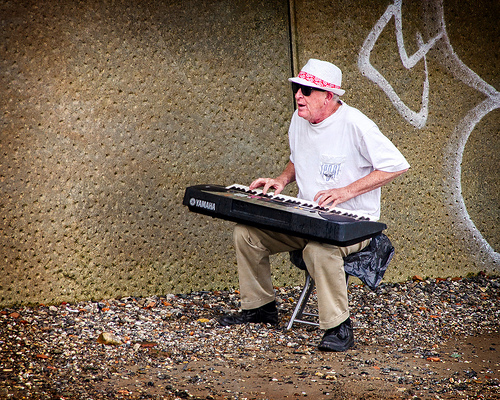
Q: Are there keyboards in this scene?
A: Yes, there is a keyboard.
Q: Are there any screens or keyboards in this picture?
A: Yes, there is a keyboard.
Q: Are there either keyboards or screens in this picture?
A: Yes, there is a keyboard.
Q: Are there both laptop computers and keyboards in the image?
A: No, there is a keyboard but no laptops.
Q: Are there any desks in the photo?
A: No, there are no desks.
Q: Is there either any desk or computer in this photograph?
A: No, there are no desks or computers.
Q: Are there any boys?
A: No, there are no boys.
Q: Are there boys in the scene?
A: No, there are no boys.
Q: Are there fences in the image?
A: No, there are no fences.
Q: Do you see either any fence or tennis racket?
A: No, there are no fences or rackets.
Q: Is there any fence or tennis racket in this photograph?
A: No, there are no fences or rackets.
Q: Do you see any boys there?
A: No, there are no boys.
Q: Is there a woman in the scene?
A: No, there are no women.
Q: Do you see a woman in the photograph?
A: No, there are no women.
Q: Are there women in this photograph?
A: No, there are no women.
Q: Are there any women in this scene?
A: No, there are no women.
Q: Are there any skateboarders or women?
A: No, there are no women or skateboarders.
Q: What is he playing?
A: The man is playing the keyboard.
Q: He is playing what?
A: The man is playing the keyboard.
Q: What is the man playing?
A: The man is playing the keyboard.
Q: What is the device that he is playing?
A: The device is a keyboard.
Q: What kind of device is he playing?
A: The man is playing the keyboard.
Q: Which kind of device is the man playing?
A: The man is playing the keyboard.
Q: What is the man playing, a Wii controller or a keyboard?
A: The man is playing a keyboard.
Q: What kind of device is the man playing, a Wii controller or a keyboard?
A: The man is playing a keyboard.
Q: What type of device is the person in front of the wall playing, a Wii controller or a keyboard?
A: The man is playing a keyboard.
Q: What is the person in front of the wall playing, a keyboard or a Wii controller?
A: The man is playing a keyboard.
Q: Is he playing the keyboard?
A: Yes, the man is playing the keyboard.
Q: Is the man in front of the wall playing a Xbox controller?
A: No, the man is playing the keyboard.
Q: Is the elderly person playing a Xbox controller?
A: No, the man is playing the keyboard.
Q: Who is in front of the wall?
A: The man is in front of the wall.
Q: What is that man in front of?
A: The man is in front of the wall.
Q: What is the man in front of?
A: The man is in front of the wall.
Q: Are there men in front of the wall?
A: Yes, there is a man in front of the wall.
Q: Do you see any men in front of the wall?
A: Yes, there is a man in front of the wall.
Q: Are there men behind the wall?
A: No, the man is in front of the wall.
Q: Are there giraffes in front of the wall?
A: No, there is a man in front of the wall.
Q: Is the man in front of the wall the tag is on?
A: Yes, the man is in front of the wall.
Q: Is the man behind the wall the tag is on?
A: No, the man is in front of the wall.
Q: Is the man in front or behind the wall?
A: The man is in front of the wall.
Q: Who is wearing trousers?
A: The man is wearing trousers.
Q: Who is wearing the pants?
A: The man is wearing trousers.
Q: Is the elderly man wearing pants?
A: Yes, the man is wearing pants.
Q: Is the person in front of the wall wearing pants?
A: Yes, the man is wearing pants.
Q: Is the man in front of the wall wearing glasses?
A: No, the man is wearing pants.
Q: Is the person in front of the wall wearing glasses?
A: No, the man is wearing pants.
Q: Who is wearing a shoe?
A: The man is wearing a shoe.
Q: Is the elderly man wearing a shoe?
A: Yes, the man is wearing a shoe.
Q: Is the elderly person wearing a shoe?
A: Yes, the man is wearing a shoe.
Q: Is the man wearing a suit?
A: No, the man is wearing a shoe.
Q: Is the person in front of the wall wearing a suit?
A: No, the man is wearing a shoe.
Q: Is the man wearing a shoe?
A: Yes, the man is wearing a shoe.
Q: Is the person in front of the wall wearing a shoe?
A: Yes, the man is wearing a shoe.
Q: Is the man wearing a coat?
A: No, the man is wearing a shoe.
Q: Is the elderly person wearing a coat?
A: No, the man is wearing a shoe.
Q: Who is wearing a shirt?
A: The man is wearing a shirt.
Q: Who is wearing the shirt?
A: The man is wearing a shirt.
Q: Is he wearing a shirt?
A: Yes, the man is wearing a shirt.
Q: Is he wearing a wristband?
A: No, the man is wearing a shirt.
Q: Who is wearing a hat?
A: The man is wearing a hat.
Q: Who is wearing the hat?
A: The man is wearing a hat.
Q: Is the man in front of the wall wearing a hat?
A: Yes, the man is wearing a hat.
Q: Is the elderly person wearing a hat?
A: Yes, the man is wearing a hat.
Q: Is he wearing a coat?
A: No, the man is wearing a hat.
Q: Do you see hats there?
A: Yes, there is a hat.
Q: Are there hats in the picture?
A: Yes, there is a hat.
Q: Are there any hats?
A: Yes, there is a hat.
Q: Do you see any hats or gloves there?
A: Yes, there is a hat.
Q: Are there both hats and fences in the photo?
A: No, there is a hat but no fences.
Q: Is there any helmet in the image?
A: No, there are no helmets.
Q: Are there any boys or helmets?
A: No, there are no helmets or boys.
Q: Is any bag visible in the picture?
A: Yes, there is a bag.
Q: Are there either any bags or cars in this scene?
A: Yes, there is a bag.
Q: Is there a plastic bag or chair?
A: Yes, there is a plastic bag.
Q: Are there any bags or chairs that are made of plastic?
A: Yes, the bag is made of plastic.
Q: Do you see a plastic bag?
A: Yes, there is a bag that is made of plastic.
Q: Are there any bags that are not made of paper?
A: Yes, there is a bag that is made of plastic.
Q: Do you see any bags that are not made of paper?
A: Yes, there is a bag that is made of plastic.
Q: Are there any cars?
A: No, there are no cars.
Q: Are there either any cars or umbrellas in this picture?
A: No, there are no cars or umbrellas.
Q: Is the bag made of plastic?
A: Yes, the bag is made of plastic.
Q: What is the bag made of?
A: The bag is made of plastic.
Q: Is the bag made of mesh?
A: No, the bag is made of plastic.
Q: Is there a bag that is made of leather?
A: No, there is a bag but it is made of plastic.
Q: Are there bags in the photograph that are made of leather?
A: No, there is a bag but it is made of plastic.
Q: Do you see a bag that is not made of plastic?
A: No, there is a bag but it is made of plastic.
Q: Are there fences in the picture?
A: No, there are no fences.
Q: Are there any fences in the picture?
A: No, there are no fences.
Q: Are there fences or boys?
A: No, there are no fences or boys.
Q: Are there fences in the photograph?
A: No, there are no fences.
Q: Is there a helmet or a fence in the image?
A: No, there are no fences or helmets.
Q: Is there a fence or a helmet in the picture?
A: No, there are no fences or helmets.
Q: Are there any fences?
A: No, there are no fences.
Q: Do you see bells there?
A: No, there are no bells.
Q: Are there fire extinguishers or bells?
A: No, there are no bells or fire extinguishers.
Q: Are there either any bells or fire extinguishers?
A: No, there are no bells or fire extinguishers.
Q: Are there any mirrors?
A: No, there are no mirrors.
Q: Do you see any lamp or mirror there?
A: No, there are no mirrors or lamps.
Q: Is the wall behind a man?
A: Yes, the wall is behind a man.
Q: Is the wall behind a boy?
A: No, the wall is behind a man.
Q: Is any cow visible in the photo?
A: No, there are no cows.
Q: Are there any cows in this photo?
A: No, there are no cows.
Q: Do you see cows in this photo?
A: No, there are no cows.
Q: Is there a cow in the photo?
A: No, there are no cows.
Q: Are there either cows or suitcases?
A: No, there are no cows or suitcases.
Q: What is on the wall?
A: The tag is on the wall.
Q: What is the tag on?
A: The tag is on the wall.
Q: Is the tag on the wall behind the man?
A: Yes, the tag is on the wall.